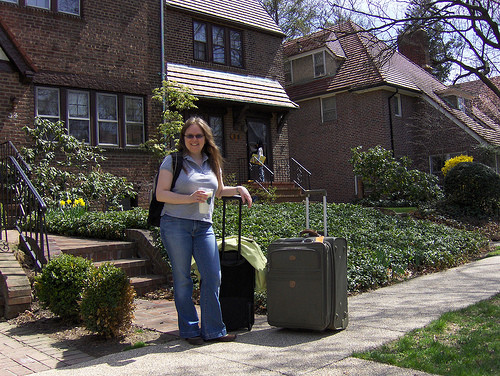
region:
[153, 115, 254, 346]
a girl is standing.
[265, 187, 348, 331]
a suitcase on the ground.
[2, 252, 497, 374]
a cement side walk.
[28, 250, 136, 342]
two small green bushes.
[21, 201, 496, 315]
an ivy gound cover.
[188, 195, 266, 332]
a sweater on a suitcase.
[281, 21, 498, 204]
a big brown house.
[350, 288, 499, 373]
grass next to sidewalk.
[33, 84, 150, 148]
four windows on a house.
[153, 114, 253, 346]
a lady with sunglasses.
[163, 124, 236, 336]
One woman is standing in pathway.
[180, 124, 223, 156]
Woman is wearing black eyeglasses.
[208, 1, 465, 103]
Roof is brown color.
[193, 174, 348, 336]
Two suitcase are in pathway.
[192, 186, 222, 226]
Lady is holding coffee mug in hand.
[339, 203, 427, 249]
Shrubs are green color.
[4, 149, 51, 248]
Rail is black color.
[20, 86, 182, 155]
Windows are attached to the wall.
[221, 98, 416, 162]
Walls are red color.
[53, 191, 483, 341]
Shadow falls on ground.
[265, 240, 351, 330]
A grey colored suitcase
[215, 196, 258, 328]
A black colored suitcase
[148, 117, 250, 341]
A woman in blue jeans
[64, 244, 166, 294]
Three front steps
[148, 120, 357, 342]
A woman ready to travel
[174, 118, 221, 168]
A woman wearing glasses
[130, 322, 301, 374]
Grey cemented floor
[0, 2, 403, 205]
Buildings made of brick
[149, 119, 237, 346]
A woman carrying a backpack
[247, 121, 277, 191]
A person in front of door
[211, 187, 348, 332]
two rolling suitcases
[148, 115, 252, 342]
a woman wearing sunglasses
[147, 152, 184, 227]
the woman's backpack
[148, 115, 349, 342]
the woman has two suitcases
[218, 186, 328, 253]
the suitcase handles are extended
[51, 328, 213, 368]
shadow on the sidewalk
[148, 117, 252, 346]
woman holding a coffee cup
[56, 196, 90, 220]
a group of bright yellow flowers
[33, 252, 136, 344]
two small bushes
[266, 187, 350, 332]
a large gray suitcase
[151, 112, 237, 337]
One lady is standing in pathway.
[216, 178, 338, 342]
Two suitcase in pathway.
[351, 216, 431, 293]
Shrubs are green color.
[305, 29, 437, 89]
Roof is brown color.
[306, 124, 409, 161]
Wall is red color.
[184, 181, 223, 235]
Lady is holding coffee mug.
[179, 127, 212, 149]
Lady is wearing black glasses.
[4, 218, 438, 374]
Shadows on ground.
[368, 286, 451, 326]
Pathway is grey color.